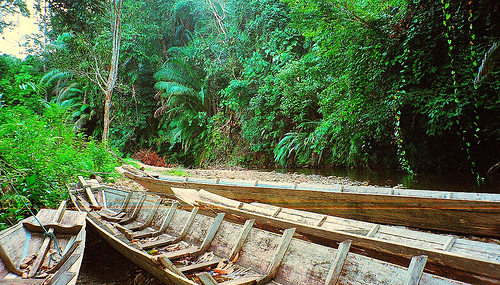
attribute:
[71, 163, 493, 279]
boats — wooden, torn, laying, wood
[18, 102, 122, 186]
plants — green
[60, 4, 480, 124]
trees — green, lush, growing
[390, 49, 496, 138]
vines — green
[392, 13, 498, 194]
bush — tall, green, small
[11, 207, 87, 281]
boat — dirty, torn, large, old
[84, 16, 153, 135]
tree — barren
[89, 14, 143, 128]
leaves — red, big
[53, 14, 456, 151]
features — green, natural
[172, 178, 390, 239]
boat — torn, upper right, second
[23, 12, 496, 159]
forest — filled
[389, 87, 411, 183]
ivy — light green, cascading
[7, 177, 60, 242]
rope — blue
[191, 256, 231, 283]
leaves — colorful, dead, dry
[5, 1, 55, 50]
sky — bright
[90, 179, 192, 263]
boat — second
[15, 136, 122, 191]
vegetation — green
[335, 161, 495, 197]
water — dark, river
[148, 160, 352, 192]
beach — small, empty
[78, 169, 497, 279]
canoes — abandoned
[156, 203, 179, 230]
slats — wooden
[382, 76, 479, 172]
vine — long, ivy, hanging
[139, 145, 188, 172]
patch — red, flowers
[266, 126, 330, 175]
ferns — green, large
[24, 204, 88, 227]
foot rest — wooden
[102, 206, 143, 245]
pieces — wood